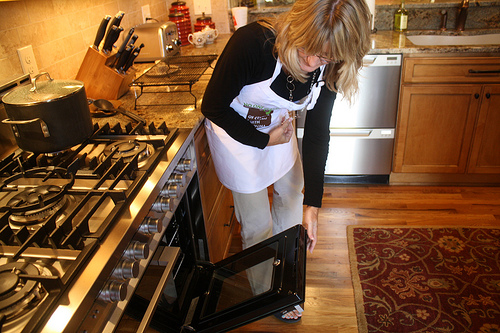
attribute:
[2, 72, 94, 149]
pot — black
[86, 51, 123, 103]
holder — wooden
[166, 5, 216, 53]
canister — red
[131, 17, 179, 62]
toaster — silver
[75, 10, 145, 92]
knives — set, kitchen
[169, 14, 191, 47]
canister — red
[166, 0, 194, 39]
canister — red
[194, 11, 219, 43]
canister — red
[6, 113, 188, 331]
grates — black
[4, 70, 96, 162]
pot — grey, black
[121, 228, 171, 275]
knob — silver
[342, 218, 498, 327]
rug — area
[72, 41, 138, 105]
holder — knife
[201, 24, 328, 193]
apron — white